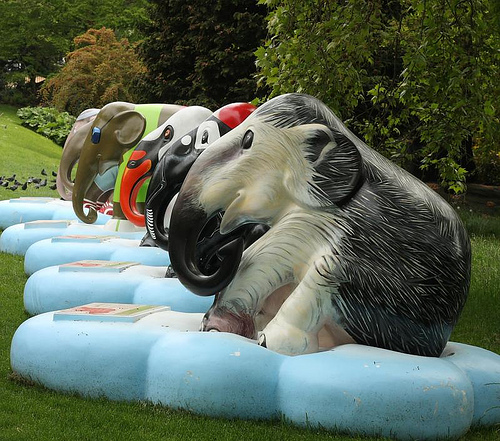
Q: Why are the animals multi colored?
A: They're painted.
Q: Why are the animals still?
A: They're statues.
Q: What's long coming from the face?
A: Trunk.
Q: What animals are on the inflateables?
A: Elephants.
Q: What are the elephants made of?
A: Plastic.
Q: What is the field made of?
A: Grass.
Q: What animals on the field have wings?
A: Birds.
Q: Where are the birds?
A: On the field.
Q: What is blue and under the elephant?
A: Stones.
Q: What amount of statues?
A: Five.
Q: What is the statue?
A: Elephant.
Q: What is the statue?
A: Elephant.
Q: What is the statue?
A: Elephant.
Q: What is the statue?
A: Elephant.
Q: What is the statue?
A: Elephant.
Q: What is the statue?
A: Elephant.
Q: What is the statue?
A: Elephant.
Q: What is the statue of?
A: Elephant.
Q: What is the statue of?
A: Elephant.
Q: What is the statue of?
A: Elephant.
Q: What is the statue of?
A: Elephant.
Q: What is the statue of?
A: Elephant.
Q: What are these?
A: Statues.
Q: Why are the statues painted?
A: For decoration.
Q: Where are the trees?
A: Behind the statues.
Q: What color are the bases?
A: Blue.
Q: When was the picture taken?
A: Daytime.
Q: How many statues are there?
A: Five.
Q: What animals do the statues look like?
A: Elephants.